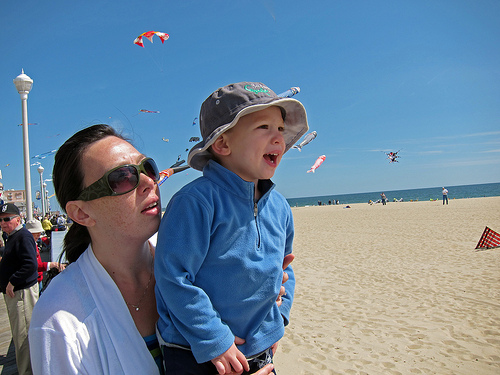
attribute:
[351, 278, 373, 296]
beach — sandy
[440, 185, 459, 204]
man — standing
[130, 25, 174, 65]
kite — red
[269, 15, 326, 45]
sky — blue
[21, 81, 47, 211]
post — white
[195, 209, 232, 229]
sweater — blue, white, black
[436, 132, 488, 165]
clouds — white, long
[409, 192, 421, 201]
ocean — blue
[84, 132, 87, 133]
hair — dark, brown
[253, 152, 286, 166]
mouth — open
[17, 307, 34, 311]
pants — tan